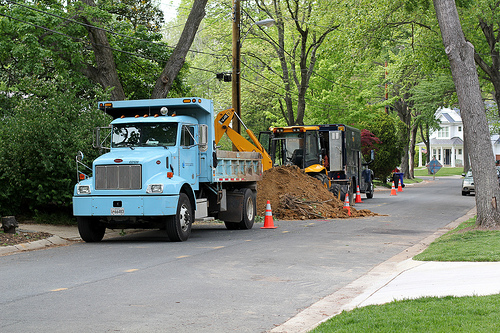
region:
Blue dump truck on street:
[69, 96, 259, 247]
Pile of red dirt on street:
[262, 159, 364, 228]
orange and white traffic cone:
[262, 196, 277, 234]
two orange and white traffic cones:
[338, 181, 363, 215]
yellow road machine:
[204, 103, 326, 223]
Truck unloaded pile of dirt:
[69, 85, 362, 253]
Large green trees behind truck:
[1, 1, 188, 217]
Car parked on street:
[461, 163, 482, 200]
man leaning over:
[389, 167, 410, 190]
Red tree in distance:
[358, 121, 382, 155]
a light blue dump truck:
[79, 96, 257, 239]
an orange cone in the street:
[261, 201, 292, 232]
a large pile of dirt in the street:
[254, 152, 376, 245]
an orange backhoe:
[214, 101, 335, 246]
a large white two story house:
[389, 91, 499, 186]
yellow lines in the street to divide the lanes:
[50, 264, 154, 307]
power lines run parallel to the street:
[221, 3, 329, 100]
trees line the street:
[398, 8, 497, 237]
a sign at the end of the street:
[413, 154, 447, 191]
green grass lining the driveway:
[326, 227, 499, 324]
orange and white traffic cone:
[246, 192, 282, 260]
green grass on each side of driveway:
[364, 231, 493, 331]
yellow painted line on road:
[0, 243, 201, 309]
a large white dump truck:
[81, 85, 326, 237]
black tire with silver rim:
[158, 193, 204, 255]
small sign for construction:
[408, 151, 451, 204]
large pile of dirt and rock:
[248, 148, 377, 244]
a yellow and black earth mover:
[231, 107, 331, 216]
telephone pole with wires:
[116, 33, 272, 95]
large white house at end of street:
[386, 80, 486, 223]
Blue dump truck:
[101, 107, 227, 234]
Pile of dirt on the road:
[263, 163, 333, 218]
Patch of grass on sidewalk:
[423, 218, 490, 279]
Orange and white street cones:
[389, 176, 404, 193]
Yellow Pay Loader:
[268, 124, 335, 201]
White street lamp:
[240, 13, 290, 45]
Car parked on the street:
[450, 160, 492, 207]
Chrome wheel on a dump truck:
[162, 199, 203, 229]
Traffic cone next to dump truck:
[252, 196, 281, 231]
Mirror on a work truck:
[367, 148, 387, 159]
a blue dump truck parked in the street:
[72, 95, 259, 241]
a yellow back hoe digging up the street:
[215, 106, 330, 188]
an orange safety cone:
[259, 198, 276, 229]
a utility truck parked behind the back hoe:
[318, 124, 374, 199]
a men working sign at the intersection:
[425, 157, 443, 181]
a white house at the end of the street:
[417, 107, 463, 161]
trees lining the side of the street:
[0, 0, 435, 86]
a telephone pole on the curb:
[229, 1, 242, 112]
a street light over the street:
[238, 17, 276, 47]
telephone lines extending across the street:
[242, 25, 292, 104]